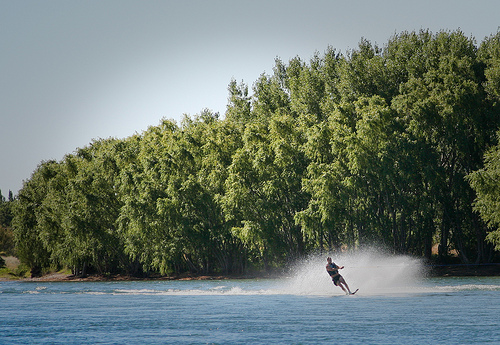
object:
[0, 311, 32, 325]
water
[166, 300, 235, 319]
ripple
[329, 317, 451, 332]
ripple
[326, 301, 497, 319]
ripple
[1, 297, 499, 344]
ripple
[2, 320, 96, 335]
ripple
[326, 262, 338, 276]
vest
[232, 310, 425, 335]
ripple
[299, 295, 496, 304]
ripple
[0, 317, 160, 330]
ripple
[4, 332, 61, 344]
ripple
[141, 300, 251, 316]
ripple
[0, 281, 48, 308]
water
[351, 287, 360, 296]
front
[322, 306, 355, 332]
water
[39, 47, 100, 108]
sky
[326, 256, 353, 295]
man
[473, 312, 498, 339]
water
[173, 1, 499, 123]
sky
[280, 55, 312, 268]
trees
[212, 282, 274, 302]
ripple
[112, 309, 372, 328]
ripple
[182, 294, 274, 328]
water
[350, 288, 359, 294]
ski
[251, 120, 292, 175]
leaves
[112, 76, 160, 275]
trees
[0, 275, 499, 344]
lake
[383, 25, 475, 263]
tree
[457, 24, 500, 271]
tree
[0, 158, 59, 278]
tree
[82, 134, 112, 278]
tree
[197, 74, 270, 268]
tree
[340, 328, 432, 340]
ripple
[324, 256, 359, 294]
skating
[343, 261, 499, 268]
cable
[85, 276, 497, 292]
waves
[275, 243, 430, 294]
water spray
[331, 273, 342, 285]
shorts